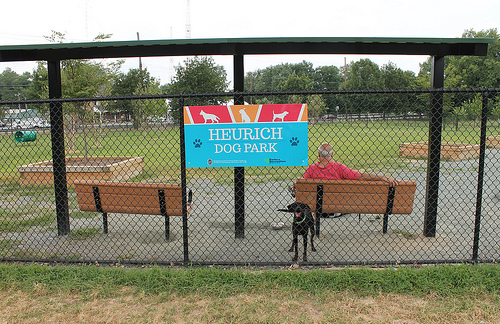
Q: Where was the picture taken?
A: It was taken at the park.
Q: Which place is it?
A: It is a park.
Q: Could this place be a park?
A: Yes, it is a park.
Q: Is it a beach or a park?
A: It is a park.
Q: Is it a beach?
A: No, it is a park.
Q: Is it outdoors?
A: Yes, it is outdoors.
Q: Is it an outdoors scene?
A: Yes, it is outdoors.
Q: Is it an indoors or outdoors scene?
A: It is outdoors.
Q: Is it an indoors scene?
A: No, it is outdoors.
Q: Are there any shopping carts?
A: No, there are no shopping carts.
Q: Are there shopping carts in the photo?
A: No, there are no shopping carts.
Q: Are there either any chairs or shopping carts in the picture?
A: No, there are no shopping carts or chairs.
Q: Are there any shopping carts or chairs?
A: No, there are no shopping carts or chairs.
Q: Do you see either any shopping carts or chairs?
A: No, there are no shopping carts or chairs.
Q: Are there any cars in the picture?
A: No, there are no cars.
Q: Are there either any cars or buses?
A: No, there are no cars or buses.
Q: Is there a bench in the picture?
A: Yes, there is a bench.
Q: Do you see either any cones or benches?
A: Yes, there is a bench.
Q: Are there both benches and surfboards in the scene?
A: No, there is a bench but no surfboards.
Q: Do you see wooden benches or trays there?
A: Yes, there is a wood bench.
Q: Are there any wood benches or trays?
A: Yes, there is a wood bench.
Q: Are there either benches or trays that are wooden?
A: Yes, the bench is wooden.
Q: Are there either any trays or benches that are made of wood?
A: Yes, the bench is made of wood.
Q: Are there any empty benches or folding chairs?
A: Yes, there is an empty bench.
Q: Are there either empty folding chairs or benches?
A: Yes, there is an empty bench.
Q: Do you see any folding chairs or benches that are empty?
A: Yes, the bench is empty.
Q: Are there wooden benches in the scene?
A: Yes, there is a wood bench.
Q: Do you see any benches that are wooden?
A: Yes, there is a bench that is wooden.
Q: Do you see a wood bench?
A: Yes, there is a bench that is made of wood.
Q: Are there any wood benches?
A: Yes, there is a bench that is made of wood.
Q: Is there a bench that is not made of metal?
A: Yes, there is a bench that is made of wood.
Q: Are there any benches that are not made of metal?
A: Yes, there is a bench that is made of wood.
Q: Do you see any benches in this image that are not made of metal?
A: Yes, there is a bench that is made of wood.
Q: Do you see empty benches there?
A: Yes, there is an empty bench.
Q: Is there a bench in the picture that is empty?
A: Yes, there is a bench that is empty.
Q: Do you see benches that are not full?
A: Yes, there is a empty bench.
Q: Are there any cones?
A: No, there are no cones.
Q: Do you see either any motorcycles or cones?
A: No, there are no cones or motorcycles.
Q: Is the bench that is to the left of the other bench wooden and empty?
A: Yes, the bench is wooden and empty.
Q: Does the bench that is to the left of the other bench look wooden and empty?
A: Yes, the bench is wooden and empty.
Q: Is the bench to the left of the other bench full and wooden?
A: No, the bench is wooden but empty.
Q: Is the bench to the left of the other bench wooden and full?
A: No, the bench is wooden but empty.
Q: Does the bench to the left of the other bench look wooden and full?
A: No, the bench is wooden but empty.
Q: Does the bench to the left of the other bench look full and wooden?
A: No, the bench is wooden but empty.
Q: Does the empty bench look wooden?
A: Yes, the bench is wooden.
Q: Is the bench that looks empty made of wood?
A: Yes, the bench is made of wood.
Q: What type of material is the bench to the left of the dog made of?
A: The bench is made of wood.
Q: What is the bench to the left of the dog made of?
A: The bench is made of wood.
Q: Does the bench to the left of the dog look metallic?
A: No, the bench is wooden.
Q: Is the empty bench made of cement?
A: No, the bench is made of wood.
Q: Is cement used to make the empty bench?
A: No, the bench is made of wood.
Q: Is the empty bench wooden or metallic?
A: The bench is wooden.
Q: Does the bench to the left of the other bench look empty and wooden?
A: Yes, the bench is empty and wooden.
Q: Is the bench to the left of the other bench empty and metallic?
A: No, the bench is empty but wooden.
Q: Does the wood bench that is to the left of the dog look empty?
A: Yes, the bench is empty.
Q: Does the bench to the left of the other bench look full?
A: No, the bench is empty.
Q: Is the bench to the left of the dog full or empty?
A: The bench is empty.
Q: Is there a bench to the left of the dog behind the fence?
A: Yes, there is a bench to the left of the dog.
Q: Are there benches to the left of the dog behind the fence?
A: Yes, there is a bench to the left of the dog.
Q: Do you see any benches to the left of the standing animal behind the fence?
A: Yes, there is a bench to the left of the dog.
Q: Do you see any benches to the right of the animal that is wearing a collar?
A: No, the bench is to the left of the dog.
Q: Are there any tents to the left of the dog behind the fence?
A: No, there is a bench to the left of the dog.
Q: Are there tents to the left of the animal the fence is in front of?
A: No, there is a bench to the left of the dog.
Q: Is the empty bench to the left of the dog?
A: Yes, the bench is to the left of the dog.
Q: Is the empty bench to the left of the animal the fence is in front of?
A: Yes, the bench is to the left of the dog.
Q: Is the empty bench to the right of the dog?
A: No, the bench is to the left of the dog.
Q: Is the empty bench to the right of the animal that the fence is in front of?
A: No, the bench is to the left of the dog.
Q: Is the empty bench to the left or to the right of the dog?
A: The bench is to the left of the dog.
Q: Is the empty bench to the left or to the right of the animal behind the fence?
A: The bench is to the left of the dog.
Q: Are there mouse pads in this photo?
A: No, there are no mouse pads.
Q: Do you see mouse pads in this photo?
A: No, there are no mouse pads.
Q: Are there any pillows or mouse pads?
A: No, there are no mouse pads or pillows.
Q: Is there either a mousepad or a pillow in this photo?
A: No, there are no mouse pads or pillows.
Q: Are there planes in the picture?
A: No, there are no planes.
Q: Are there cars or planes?
A: No, there are no planes or cars.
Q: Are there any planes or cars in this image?
A: No, there are no planes or cars.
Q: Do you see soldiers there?
A: No, there are no soldiers.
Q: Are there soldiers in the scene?
A: No, there are no soldiers.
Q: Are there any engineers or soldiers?
A: No, there are no soldiers or engineers.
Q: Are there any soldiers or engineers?
A: No, there are no soldiers or engineers.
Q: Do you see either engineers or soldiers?
A: No, there are no soldiers or engineers.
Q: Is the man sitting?
A: Yes, the man is sitting.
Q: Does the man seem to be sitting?
A: Yes, the man is sitting.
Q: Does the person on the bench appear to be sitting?
A: Yes, the man is sitting.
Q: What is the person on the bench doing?
A: The man is sitting.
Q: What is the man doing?
A: The man is sitting.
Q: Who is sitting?
A: The man is sitting.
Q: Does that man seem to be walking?
A: No, the man is sitting.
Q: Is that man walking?
A: No, the man is sitting.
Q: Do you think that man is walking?
A: No, the man is sitting.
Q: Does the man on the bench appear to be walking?
A: No, the man is sitting.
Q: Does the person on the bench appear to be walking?
A: No, the man is sitting.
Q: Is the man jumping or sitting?
A: The man is sitting.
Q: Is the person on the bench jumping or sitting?
A: The man is sitting.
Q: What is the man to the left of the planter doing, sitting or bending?
A: The man is sitting.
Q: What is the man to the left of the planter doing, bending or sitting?
A: The man is sitting.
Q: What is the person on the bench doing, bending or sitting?
A: The man is sitting.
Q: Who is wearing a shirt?
A: The man is wearing a shirt.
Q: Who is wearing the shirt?
A: The man is wearing a shirt.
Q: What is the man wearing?
A: The man is wearing a shirt.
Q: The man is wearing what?
A: The man is wearing a shirt.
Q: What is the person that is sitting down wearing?
A: The man is wearing a shirt.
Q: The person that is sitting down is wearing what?
A: The man is wearing a shirt.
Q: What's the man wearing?
A: The man is wearing a shirt.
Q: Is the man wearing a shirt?
A: Yes, the man is wearing a shirt.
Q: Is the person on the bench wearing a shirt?
A: Yes, the man is wearing a shirt.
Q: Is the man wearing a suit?
A: No, the man is wearing a shirt.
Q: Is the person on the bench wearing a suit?
A: No, the man is wearing a shirt.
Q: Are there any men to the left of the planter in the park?
A: Yes, there is a man to the left of the planter.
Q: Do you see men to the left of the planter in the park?
A: Yes, there is a man to the left of the planter.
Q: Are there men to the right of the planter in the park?
A: No, the man is to the left of the planter.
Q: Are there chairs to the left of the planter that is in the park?
A: No, there is a man to the left of the planter.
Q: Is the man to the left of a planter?
A: Yes, the man is to the left of a planter.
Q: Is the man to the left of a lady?
A: No, the man is to the left of a planter.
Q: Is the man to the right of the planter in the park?
A: No, the man is to the left of the planter.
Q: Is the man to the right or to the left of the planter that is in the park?
A: The man is to the left of the planter.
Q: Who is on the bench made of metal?
A: The man is on the bench.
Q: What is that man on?
A: The man is on the bench.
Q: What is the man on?
A: The man is on the bench.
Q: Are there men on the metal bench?
A: Yes, there is a man on the bench.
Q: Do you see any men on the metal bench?
A: Yes, there is a man on the bench.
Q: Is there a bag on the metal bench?
A: No, there is a man on the bench.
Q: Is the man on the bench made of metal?
A: Yes, the man is on the bench.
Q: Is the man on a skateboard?
A: No, the man is on the bench.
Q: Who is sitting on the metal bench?
A: The man is sitting on the bench.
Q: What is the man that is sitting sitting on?
A: The man is sitting on the bench.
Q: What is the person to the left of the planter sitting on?
A: The man is sitting on the bench.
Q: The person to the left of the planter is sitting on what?
A: The man is sitting on the bench.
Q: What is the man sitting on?
A: The man is sitting on the bench.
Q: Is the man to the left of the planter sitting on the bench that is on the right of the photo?
A: Yes, the man is sitting on the bench.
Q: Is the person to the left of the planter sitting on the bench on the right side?
A: Yes, the man is sitting on the bench.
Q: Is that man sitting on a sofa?
A: No, the man is sitting on the bench.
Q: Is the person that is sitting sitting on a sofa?
A: No, the man is sitting on the bench.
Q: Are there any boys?
A: No, there are no boys.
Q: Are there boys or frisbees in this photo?
A: No, there are no boys or frisbees.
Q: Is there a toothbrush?
A: No, there are no toothbrushes.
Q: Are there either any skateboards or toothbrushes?
A: No, there are no toothbrushes or skateboards.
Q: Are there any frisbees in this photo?
A: No, there are no frisbees.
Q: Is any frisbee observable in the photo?
A: No, there are no frisbees.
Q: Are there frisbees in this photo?
A: No, there are no frisbees.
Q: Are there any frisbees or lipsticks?
A: No, there are no frisbees or lipsticks.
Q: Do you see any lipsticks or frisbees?
A: No, there are no frisbees or lipsticks.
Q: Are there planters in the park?
A: Yes, there is a planter in the park.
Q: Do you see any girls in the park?
A: No, there is a planter in the park.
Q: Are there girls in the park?
A: No, there is a planter in the park.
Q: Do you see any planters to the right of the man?
A: Yes, there is a planter to the right of the man.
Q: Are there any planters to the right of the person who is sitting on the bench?
A: Yes, there is a planter to the right of the man.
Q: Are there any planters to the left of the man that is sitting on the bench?
A: No, the planter is to the right of the man.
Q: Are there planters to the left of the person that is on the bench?
A: No, the planter is to the right of the man.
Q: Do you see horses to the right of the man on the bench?
A: No, there is a planter to the right of the man.